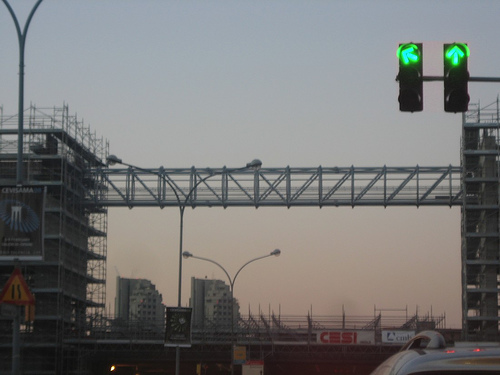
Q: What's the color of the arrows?
A: Green.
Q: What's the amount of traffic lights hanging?
A: Two.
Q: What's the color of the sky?
A: Grey.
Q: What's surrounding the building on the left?
A: Scaffolding.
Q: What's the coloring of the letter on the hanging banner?
A: Red.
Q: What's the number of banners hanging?
A: Two.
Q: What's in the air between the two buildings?
A: Walkway.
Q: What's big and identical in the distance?
A: Buildings.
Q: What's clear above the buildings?
A: Sky.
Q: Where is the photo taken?
A: City.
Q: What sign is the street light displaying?
A: Go.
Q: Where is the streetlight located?
A: Top right of photo.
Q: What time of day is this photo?
A: Evening.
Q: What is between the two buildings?
A: A structure.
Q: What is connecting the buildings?
A: A walkway.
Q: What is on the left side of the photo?
A: Building under construction?.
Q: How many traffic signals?
A: 2.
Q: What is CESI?
A: Letters on a sign.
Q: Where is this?
A: In a city.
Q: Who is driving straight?
A: A vehicle with a roof rack.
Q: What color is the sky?
A: Gray.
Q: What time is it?
A: About dusk.